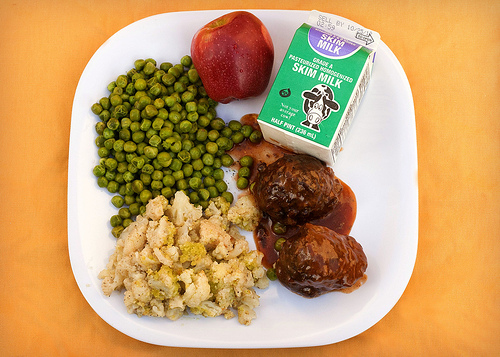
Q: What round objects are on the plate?
A: Peas.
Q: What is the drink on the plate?
A: Milk.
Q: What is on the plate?
A: Food.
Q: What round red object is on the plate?
A: Apple.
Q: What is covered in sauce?
A: Meatballs.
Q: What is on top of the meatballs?
A: Sauce.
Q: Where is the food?
A: On a plate.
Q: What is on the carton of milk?
A: Cow.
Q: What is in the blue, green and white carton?
A: Skim Milk.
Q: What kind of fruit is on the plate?
A: A red apple.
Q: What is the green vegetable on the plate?
A: Green peas.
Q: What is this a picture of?
A: A plate of food.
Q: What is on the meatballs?
A: Sauce.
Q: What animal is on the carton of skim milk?
A: A black and white cow.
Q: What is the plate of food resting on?
A: An orange tabletop.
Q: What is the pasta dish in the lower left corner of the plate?
A: Macaroni and cheese.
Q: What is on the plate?
A: Peas.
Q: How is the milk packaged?
A: In a carton.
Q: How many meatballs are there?
A: Two.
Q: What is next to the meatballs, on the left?
A: Stuffing.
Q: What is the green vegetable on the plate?
A: Peas.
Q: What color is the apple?
A: Red.